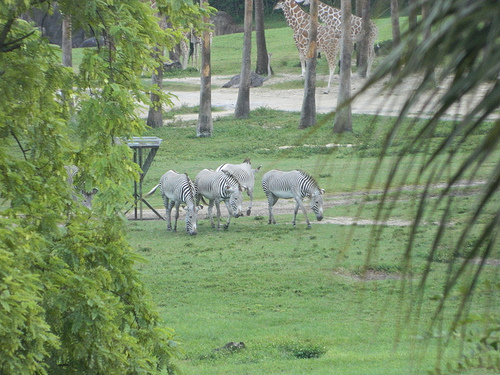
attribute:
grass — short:
[40, 13, 499, 371]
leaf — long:
[275, 24, 457, 174]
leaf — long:
[336, 54, 415, 215]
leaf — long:
[439, 229, 499, 354]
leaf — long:
[406, 128, 498, 352]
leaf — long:
[358, 69, 498, 321]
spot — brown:
[319, 32, 324, 45]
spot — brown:
[330, 30, 336, 37]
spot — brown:
[323, 30, 331, 40]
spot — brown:
[301, 28, 309, 38]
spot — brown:
[292, 5, 302, 13]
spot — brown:
[354, 16, 362, 27]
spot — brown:
[352, 14, 355, 24]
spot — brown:
[331, 8, 341, 13]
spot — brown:
[327, 6, 333, 14]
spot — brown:
[327, 27, 333, 30]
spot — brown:
[293, 8, 306, 18]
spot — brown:
[295, 14, 305, 24]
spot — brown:
[317, 33, 327, 43]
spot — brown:
[327, 47, 333, 57]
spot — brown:
[327, 5, 332, 13]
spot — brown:
[333, 5, 341, 15]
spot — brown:
[316, 11, 324, 16]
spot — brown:
[328, 19, 338, 28]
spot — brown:
[347, 13, 355, 22]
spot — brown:
[316, 6, 325, 14]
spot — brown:
[320, 10, 330, 19]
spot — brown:
[325, 8, 335, 16]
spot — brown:
[333, 6, 339, 14]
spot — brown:
[357, 16, 362, 29]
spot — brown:
[298, 23, 310, 45]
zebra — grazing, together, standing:
[261, 168, 326, 228]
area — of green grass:
[156, 239, 321, 330]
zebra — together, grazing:
[142, 167, 203, 237]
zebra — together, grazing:
[189, 165, 244, 234]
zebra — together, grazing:
[214, 158, 263, 217]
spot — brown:
[289, 9, 298, 24]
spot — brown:
[320, 9, 328, 22]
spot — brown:
[297, 38, 306, 47]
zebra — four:
[157, 164, 197, 236]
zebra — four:
[191, 160, 236, 230]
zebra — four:
[219, 155, 257, 217]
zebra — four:
[259, 153, 328, 234]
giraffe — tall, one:
[262, 4, 327, 86]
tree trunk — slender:
[232, 1, 257, 120]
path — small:
[81, 179, 477, 220]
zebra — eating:
[255, 159, 329, 233]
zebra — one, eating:
[155, 166, 205, 237]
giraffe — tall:
[270, 0, 346, 97]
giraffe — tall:
[296, 1, 377, 85]